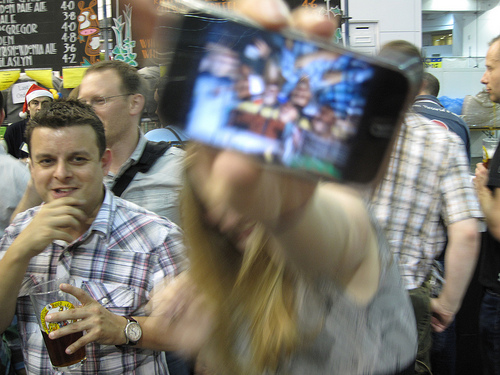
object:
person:
[236, 0, 337, 40]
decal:
[38, 300, 77, 336]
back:
[358, 115, 488, 291]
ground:
[460, 115, 485, 152]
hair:
[176, 140, 361, 375]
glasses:
[87, 91, 130, 109]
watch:
[115, 315, 143, 350]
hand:
[45, 283, 126, 355]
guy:
[472, 31, 499, 374]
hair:
[23, 100, 106, 160]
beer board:
[0, 0, 84, 69]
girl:
[151, 140, 419, 373]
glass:
[28, 276, 91, 373]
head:
[76, 59, 150, 143]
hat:
[19, 82, 56, 120]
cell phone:
[156, 10, 411, 185]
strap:
[107, 139, 175, 198]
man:
[75, 60, 188, 228]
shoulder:
[138, 131, 186, 175]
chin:
[45, 195, 83, 206]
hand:
[20, 190, 90, 256]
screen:
[185, 25, 377, 185]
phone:
[146, 4, 415, 190]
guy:
[0, 100, 193, 375]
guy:
[337, 40, 488, 375]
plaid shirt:
[3, 192, 189, 374]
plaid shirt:
[368, 110, 487, 293]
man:
[5, 83, 55, 158]